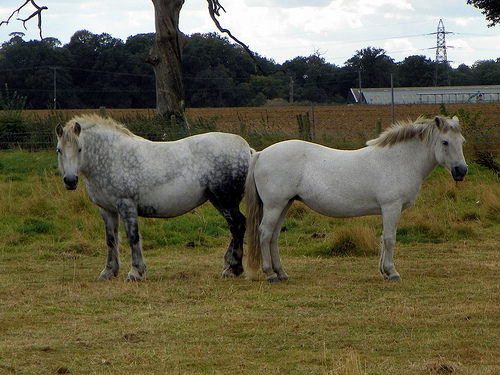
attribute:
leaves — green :
[1, 32, 499, 99]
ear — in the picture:
[70, 117, 86, 136]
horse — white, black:
[21, 70, 251, 304]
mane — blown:
[361, 107, 461, 146]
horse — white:
[238, 108, 473, 284]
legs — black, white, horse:
[89, 221, 154, 283]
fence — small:
[12, 105, 498, 156]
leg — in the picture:
[116, 197, 153, 285]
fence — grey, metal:
[11, 67, 498, 119]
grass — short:
[0, 152, 499, 372]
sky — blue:
[3, 0, 498, 78]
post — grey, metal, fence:
[308, 100, 315, 140]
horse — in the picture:
[50, 112, 256, 284]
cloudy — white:
[215, 7, 477, 72]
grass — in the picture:
[248, 277, 449, 353]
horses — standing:
[53, 110, 472, 285]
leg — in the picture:
[269, 223, 292, 280]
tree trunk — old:
[139, 0, 195, 158]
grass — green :
[172, 291, 329, 346]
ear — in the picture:
[58, 129, 65, 138]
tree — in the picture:
[2, 2, 269, 140]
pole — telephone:
[428, 18, 452, 92]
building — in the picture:
[333, 54, 493, 122]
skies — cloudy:
[4, 6, 497, 70]